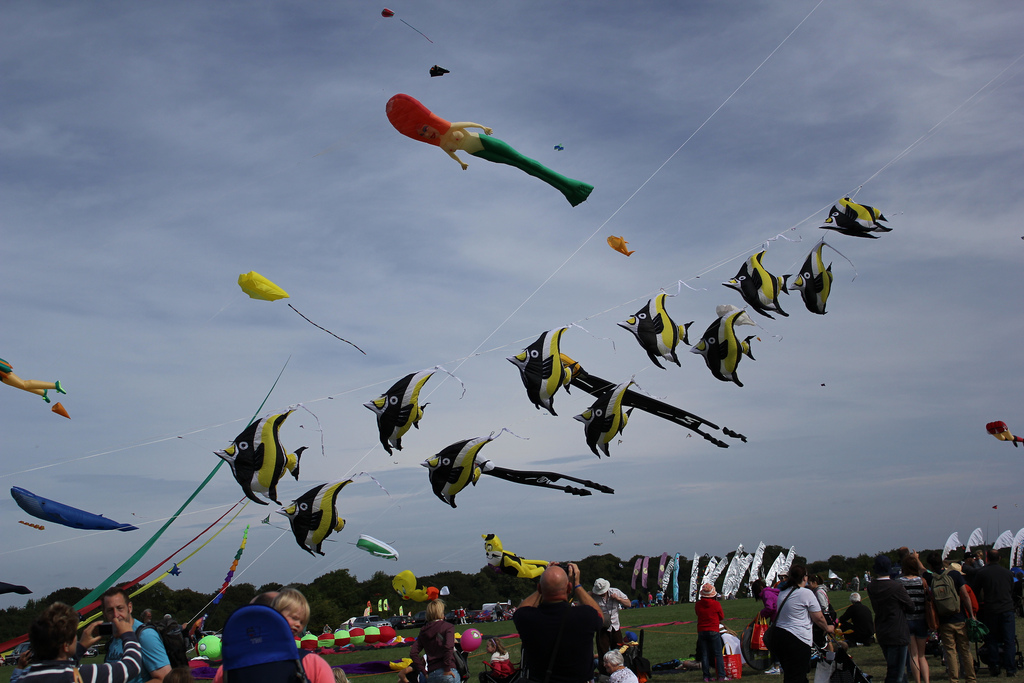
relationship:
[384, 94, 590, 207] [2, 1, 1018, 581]
mermaid kite in sky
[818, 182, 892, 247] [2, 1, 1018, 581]
kite in sky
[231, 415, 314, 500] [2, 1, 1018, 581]
kite in sky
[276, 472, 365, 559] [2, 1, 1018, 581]
kite in sky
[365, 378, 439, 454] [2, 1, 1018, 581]
kite in sky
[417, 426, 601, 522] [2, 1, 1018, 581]
kite in sky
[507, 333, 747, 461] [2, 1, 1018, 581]
kite in sky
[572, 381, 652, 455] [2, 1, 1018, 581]
kite in sky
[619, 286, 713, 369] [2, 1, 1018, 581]
kite in sky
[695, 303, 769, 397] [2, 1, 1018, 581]
kite in sky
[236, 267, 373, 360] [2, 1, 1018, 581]
kite flying in sky